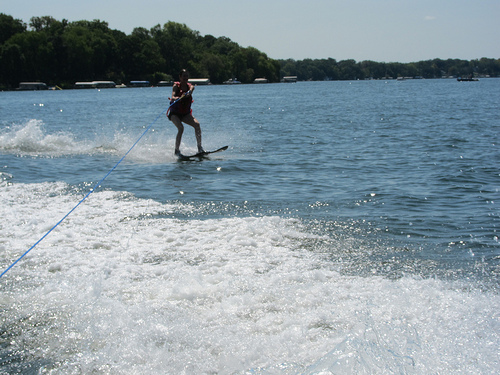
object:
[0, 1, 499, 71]
sky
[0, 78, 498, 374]
water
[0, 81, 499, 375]
ripple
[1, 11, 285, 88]
trees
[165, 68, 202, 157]
person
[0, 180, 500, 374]
wake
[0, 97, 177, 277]
cord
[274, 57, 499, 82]
trees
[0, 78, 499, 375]
lake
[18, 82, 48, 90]
dock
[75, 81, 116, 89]
dock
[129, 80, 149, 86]
dock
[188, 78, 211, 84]
dock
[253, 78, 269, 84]
dock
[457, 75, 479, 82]
boat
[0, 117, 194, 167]
wake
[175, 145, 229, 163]
skis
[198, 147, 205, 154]
foot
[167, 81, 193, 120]
vest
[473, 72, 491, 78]
house